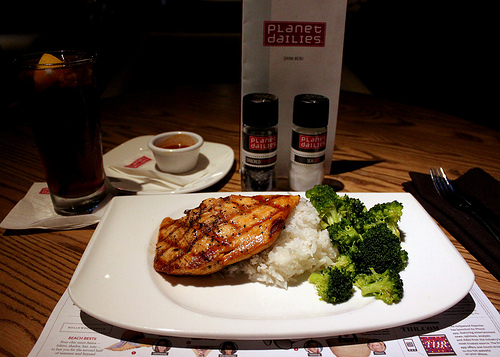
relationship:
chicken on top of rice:
[153, 196, 300, 278] [223, 192, 338, 286]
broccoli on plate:
[306, 183, 408, 306] [70, 193, 476, 338]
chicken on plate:
[153, 196, 300, 278] [70, 193, 476, 338]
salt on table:
[290, 92, 331, 191] [3, 90, 499, 354]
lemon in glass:
[37, 53, 65, 81] [17, 51, 111, 212]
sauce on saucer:
[148, 132, 202, 173] [101, 132, 238, 194]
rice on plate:
[223, 192, 338, 286] [70, 193, 476, 338]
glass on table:
[17, 51, 111, 212] [3, 90, 499, 354]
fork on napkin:
[430, 167, 500, 236] [403, 166, 500, 284]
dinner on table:
[155, 185, 407, 308] [3, 90, 499, 354]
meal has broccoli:
[155, 185, 407, 308] [306, 183, 408, 306]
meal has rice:
[155, 185, 407, 308] [223, 192, 338, 286]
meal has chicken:
[155, 185, 407, 308] [153, 196, 300, 278]